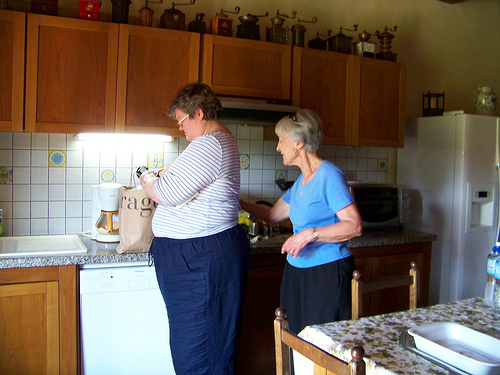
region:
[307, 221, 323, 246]
gold watch on left arm of lady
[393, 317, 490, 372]
oblong white baking dish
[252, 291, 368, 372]
chair back with knobs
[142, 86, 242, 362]
woman going through back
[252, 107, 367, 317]
woman looking at woman in front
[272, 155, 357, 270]
blue shirt of blonde woman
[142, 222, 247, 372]
purple pants of woman in front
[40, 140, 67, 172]
yellow and blue ceramic tile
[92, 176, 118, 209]
white candle on stand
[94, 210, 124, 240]
candle stand on countertop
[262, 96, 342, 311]
older woman helping with groceries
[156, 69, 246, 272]
lady checking her groceries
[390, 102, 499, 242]
white refrigerator with icemaker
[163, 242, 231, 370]
big blue jeans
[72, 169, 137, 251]
small white coffee maker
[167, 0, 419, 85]
big spice rack on cabinets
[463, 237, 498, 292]
bottles of zephyrhills water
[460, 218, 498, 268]
zephyrhills bottled water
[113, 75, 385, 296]
two friends unpacking groceries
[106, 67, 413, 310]
two ladies coming back from shopping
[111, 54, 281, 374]
woman in blue pants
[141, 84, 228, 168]
woman wearing eye glasses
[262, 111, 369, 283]
woman in blue shirt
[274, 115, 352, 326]
woman in dark colored pants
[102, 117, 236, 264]
woman with brown paper bag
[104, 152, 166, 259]
brown paper bag with black letters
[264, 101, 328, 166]
sunglasses on womans head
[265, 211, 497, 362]
two chairs at kitchen table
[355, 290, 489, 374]
white dish on table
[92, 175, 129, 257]
coffee pot on counter top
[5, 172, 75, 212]
red and white tiles on wall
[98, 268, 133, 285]
small dot on white dishwasher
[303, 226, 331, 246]
silver watch on woman's hand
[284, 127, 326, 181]
veins in woman's neck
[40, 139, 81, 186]
small yellow and blue tile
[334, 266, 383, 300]
brown orb on chair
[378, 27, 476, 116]
shadow cast on the wall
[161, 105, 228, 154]
glasses on woman's face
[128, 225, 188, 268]
string on woman's blue pants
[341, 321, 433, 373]
gold and white table cloth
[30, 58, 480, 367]
Two women standing in a kitchen.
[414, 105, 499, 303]
A white side by side refrigerator.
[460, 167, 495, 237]
Dispenser in refrigerator door.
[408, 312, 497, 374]
A long white cooking dish.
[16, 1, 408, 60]
A collection of coffee grinders.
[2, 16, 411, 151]
Overhead wooden kitchen cabinets.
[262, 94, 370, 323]
A woman with grey hair.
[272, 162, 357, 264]
A light blue shirt.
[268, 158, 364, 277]
A short sleeve shirt.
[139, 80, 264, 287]
Woman in a striped shirt.